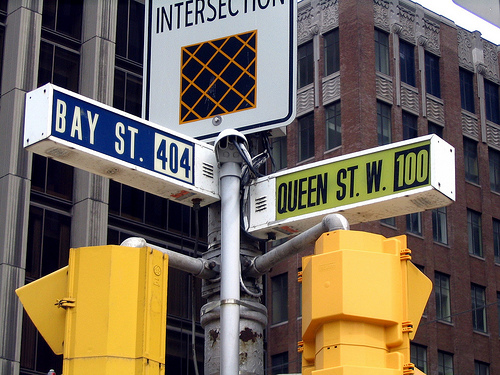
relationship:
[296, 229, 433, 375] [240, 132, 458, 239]
light under street sign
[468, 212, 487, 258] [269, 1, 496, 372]
window on building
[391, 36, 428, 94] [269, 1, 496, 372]
window on building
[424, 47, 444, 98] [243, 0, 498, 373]
window on building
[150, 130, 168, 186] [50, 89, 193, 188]
number 4 on sign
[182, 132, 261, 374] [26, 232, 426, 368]
pole holding lights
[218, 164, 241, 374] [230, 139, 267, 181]
pole with wires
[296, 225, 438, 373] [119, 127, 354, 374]
light on pipe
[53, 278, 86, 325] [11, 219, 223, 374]
fastener on streetlight